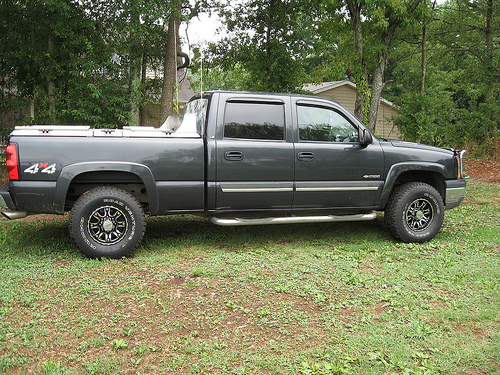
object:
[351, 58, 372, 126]
vine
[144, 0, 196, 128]
tree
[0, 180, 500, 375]
grass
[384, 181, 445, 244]
tire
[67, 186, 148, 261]
tire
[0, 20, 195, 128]
house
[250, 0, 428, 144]
tree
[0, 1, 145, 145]
tree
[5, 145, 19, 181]
light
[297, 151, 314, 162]
handle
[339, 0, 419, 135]
tree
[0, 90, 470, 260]
pickup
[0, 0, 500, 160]
trees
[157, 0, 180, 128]
trunk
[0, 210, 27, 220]
muffler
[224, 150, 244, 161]
handle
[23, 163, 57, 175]
4x4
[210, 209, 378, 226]
board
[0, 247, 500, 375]
yard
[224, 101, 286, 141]
window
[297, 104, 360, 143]
window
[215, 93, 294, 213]
door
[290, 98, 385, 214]
door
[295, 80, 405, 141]
house